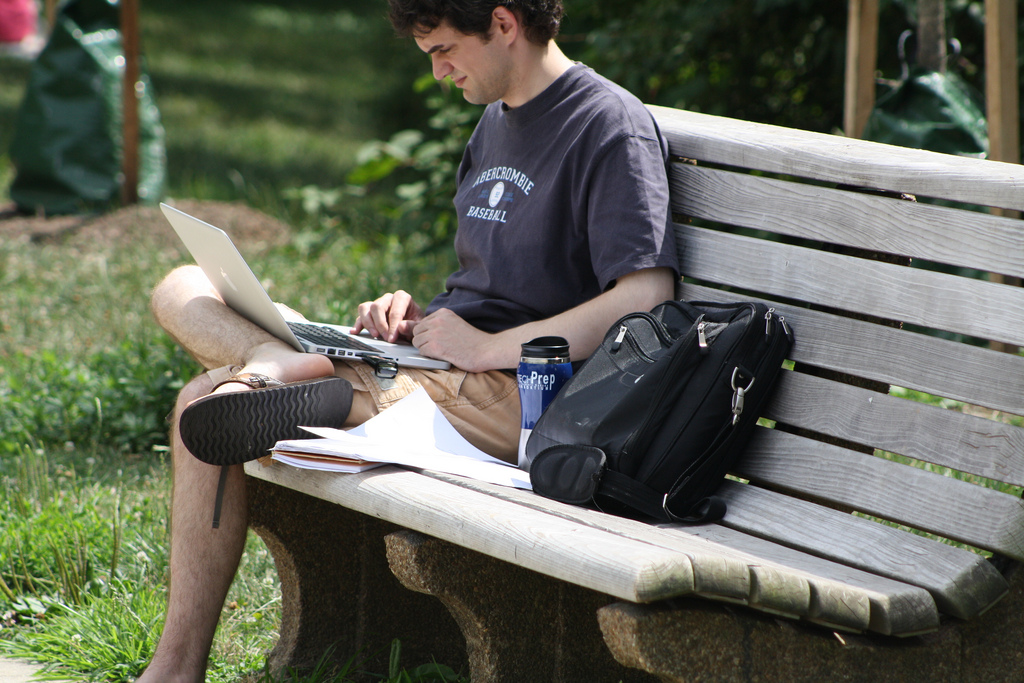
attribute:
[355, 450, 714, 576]
bench — wood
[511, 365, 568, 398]
lettering — white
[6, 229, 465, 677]
grass — green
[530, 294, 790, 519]
bag — black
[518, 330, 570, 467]
coffee mug — blue, black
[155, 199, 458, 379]
laptop — grey